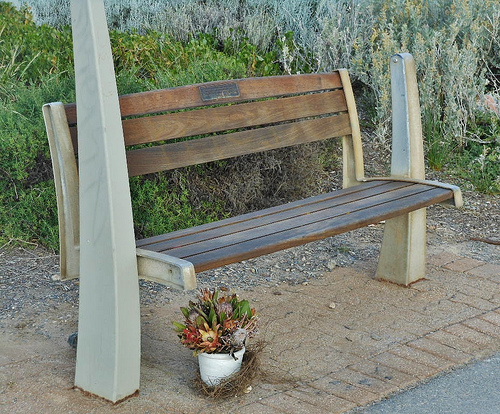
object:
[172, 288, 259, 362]
leaves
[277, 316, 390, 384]
pot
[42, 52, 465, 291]
back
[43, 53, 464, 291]
bench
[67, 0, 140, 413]
pole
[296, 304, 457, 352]
brick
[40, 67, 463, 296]
string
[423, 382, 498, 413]
cement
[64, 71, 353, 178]
board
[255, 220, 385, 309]
rocks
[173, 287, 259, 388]
plant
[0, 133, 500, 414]
ground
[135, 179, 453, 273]
board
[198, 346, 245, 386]
flower pot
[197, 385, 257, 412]
twigs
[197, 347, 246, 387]
pot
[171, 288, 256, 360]
flower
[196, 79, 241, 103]
plaque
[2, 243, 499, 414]
sidewalk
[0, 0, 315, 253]
bush